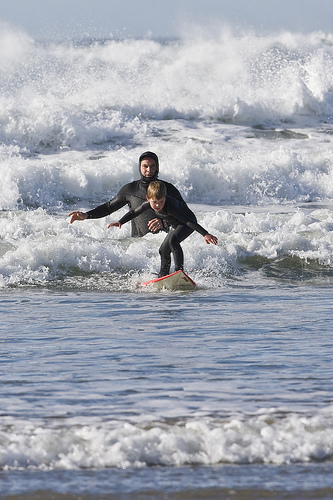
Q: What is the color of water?
A: Blue.